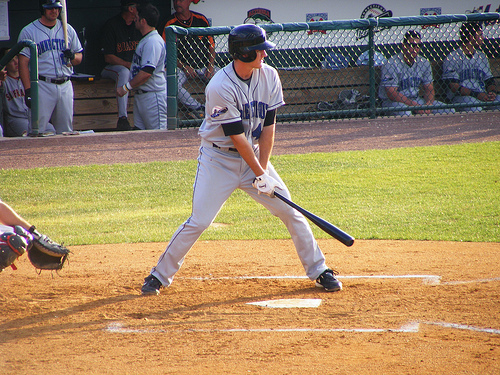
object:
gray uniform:
[149, 62, 328, 287]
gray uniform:
[123, 32, 168, 129]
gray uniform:
[378, 27, 454, 115]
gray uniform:
[441, 46, 498, 108]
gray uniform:
[15, 17, 86, 131]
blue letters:
[237, 100, 268, 120]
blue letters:
[37, 38, 68, 54]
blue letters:
[459, 65, 487, 81]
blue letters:
[132, 55, 143, 67]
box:
[104, 271, 500, 335]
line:
[205, 271, 447, 286]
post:
[162, 23, 179, 133]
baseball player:
[378, 30, 456, 115]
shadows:
[1, 285, 322, 341]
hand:
[251, 176, 266, 195]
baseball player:
[441, 20, 499, 111]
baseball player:
[115, 5, 168, 130]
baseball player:
[16, 1, 83, 136]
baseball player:
[161, 0, 217, 117]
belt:
[211, 142, 237, 149]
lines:
[111, 319, 498, 337]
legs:
[152, 171, 231, 276]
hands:
[115, 84, 127, 97]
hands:
[478, 90, 494, 101]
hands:
[411, 105, 425, 115]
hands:
[20, 87, 35, 103]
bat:
[56, 0, 72, 52]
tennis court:
[0, 1, 500, 375]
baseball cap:
[228, 24, 277, 54]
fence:
[164, 14, 498, 136]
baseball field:
[2, 106, 498, 373]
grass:
[411, 143, 463, 210]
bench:
[12, 57, 496, 137]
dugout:
[4, 2, 490, 147]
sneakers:
[140, 273, 167, 295]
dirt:
[8, 250, 499, 357]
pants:
[151, 148, 329, 285]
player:
[18, 2, 83, 136]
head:
[228, 22, 270, 68]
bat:
[274, 181, 356, 247]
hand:
[255, 173, 285, 198]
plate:
[245, 297, 323, 309]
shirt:
[195, 60, 285, 150]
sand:
[1, 239, 498, 373]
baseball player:
[140, 22, 355, 296]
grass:
[47, 167, 160, 227]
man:
[94, 7, 141, 128]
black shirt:
[105, 20, 137, 59]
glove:
[26, 235, 69, 271]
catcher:
[0, 197, 74, 280]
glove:
[252, 172, 284, 198]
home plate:
[231, 268, 349, 336]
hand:
[26, 230, 68, 270]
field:
[2, 112, 493, 371]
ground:
[0, 110, 494, 371]